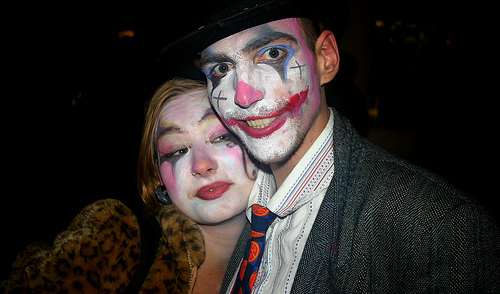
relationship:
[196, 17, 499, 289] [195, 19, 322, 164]
man with a painted face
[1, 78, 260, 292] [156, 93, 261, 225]
woman with a painted face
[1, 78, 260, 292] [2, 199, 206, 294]
woman wearing a coat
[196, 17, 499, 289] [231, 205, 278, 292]
man wearing a necktie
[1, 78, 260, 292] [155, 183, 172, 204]
woman wearing an earring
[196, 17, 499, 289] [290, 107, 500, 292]
man wearing a jacket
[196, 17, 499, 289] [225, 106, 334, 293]
man wearing a shirt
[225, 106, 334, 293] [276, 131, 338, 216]
shirt has stripes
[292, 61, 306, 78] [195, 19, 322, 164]
cross on mans face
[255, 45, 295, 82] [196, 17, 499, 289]
outline around eye of man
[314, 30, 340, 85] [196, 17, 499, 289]
ear of man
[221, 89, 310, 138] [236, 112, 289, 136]
lipstick smeared around lips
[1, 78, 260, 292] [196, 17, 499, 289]
woman cuddling with man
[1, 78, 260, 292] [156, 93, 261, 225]
woman has a painted face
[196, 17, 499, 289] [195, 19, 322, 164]
man has a painted face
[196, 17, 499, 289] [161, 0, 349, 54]
man wearing a hat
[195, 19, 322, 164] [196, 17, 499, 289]
face of man